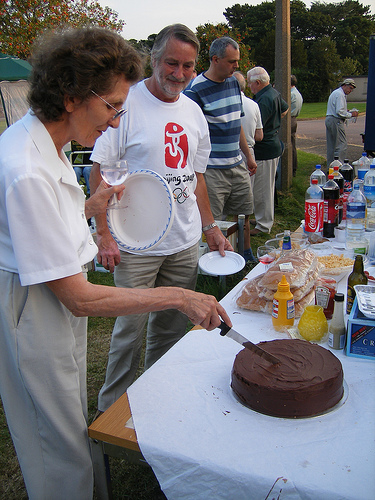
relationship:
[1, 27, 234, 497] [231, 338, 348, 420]
woman cuts cake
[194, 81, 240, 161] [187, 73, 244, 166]
stripes on shirt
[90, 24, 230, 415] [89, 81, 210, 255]
man wears white t-shirt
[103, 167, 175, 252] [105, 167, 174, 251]
plate has trim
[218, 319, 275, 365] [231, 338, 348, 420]
knife cutting in cake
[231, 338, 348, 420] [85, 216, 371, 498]
cake on table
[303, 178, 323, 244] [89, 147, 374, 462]
coca cola on table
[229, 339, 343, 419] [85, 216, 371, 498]
chocolate on table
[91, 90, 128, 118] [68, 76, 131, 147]
glasses on face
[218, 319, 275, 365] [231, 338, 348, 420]
knife slicing cake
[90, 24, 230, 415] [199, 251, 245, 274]
man holding plate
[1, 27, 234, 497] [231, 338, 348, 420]
woman cutting cake